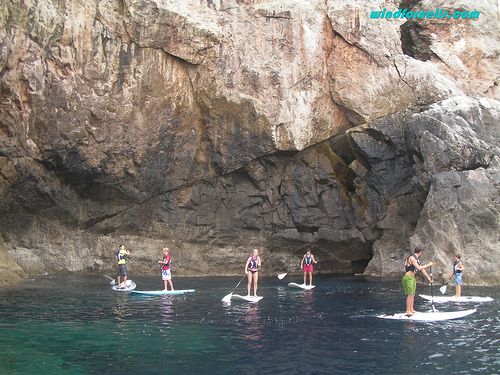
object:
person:
[453, 254, 464, 295]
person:
[399, 248, 424, 314]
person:
[244, 248, 263, 293]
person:
[113, 242, 132, 287]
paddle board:
[418, 291, 494, 307]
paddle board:
[374, 309, 478, 324]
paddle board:
[285, 282, 316, 291]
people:
[107, 232, 273, 304]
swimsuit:
[246, 256, 263, 276]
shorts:
[302, 265, 312, 273]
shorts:
[400, 271, 417, 296]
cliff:
[0, 0, 500, 279]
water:
[0, 327, 500, 374]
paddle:
[422, 268, 437, 312]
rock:
[293, 186, 389, 248]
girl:
[240, 247, 270, 298]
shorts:
[453, 271, 465, 286]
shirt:
[161, 255, 172, 271]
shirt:
[114, 250, 130, 270]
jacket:
[450, 258, 464, 279]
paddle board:
[109, 277, 136, 291]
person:
[158, 243, 176, 292]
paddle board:
[131, 287, 198, 296]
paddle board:
[229, 292, 267, 303]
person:
[299, 247, 317, 285]